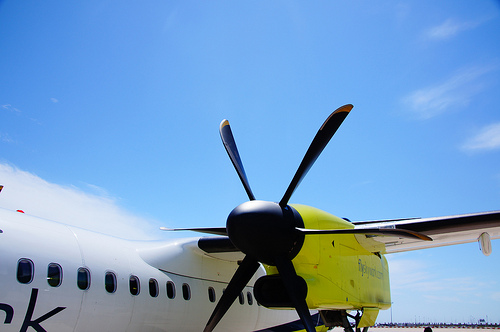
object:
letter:
[0, 288, 65, 330]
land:
[338, 325, 499, 332]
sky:
[0, 0, 499, 319]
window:
[45, 262, 65, 288]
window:
[181, 283, 192, 300]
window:
[129, 275, 140, 295]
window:
[16, 258, 36, 286]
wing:
[333, 211, 500, 260]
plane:
[1, 105, 498, 332]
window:
[207, 284, 217, 303]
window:
[146, 276, 160, 299]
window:
[77, 267, 91, 291]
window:
[166, 280, 176, 299]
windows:
[234, 292, 254, 307]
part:
[260, 202, 393, 332]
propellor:
[198, 102, 354, 331]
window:
[104, 270, 119, 294]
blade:
[278, 103, 355, 208]